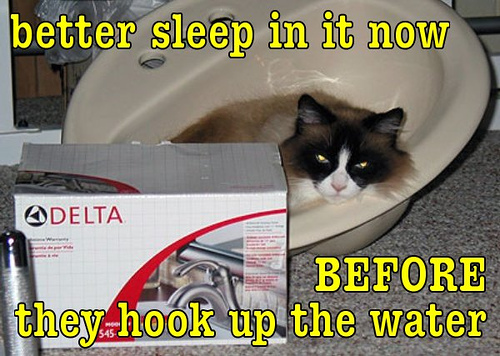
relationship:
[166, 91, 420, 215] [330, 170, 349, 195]
cat has a nose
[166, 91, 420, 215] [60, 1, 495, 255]
cat laying in sink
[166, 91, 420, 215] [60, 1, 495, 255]
cat laying inside sink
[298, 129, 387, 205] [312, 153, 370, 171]
face has eyes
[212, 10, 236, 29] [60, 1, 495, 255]
hole in top of sink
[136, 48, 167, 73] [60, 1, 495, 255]
hole in top of sink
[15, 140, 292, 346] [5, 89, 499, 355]
box on countertop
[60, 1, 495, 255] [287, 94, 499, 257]
sink has an edge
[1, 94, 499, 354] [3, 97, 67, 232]
floor has a part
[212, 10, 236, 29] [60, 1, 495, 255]
hole in sink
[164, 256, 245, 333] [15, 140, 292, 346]
faucet pictured on box